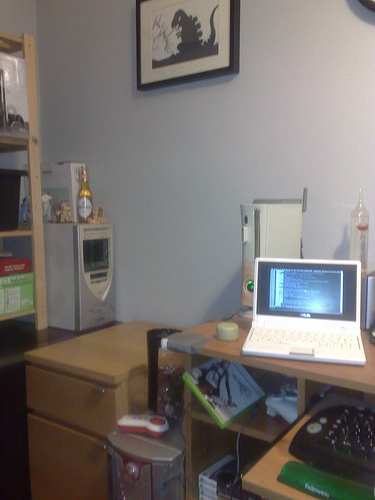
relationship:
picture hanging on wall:
[136, 1, 241, 92] [38, 1, 374, 327]